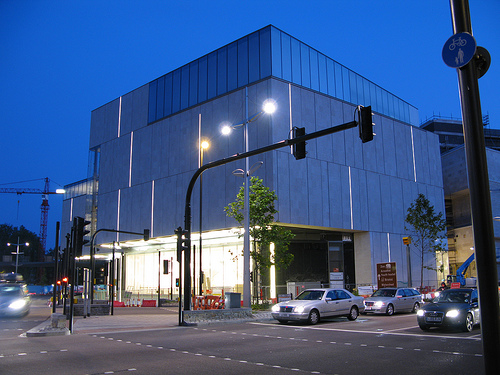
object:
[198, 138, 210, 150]
lights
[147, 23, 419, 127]
row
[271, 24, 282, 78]
window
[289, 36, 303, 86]
window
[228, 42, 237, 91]
window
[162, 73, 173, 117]
window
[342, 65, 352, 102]
window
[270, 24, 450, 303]
side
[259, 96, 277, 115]
light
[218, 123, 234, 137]
light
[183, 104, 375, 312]
light pole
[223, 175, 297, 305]
tree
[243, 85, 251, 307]
pole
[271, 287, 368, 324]
car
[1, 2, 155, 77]
blue sky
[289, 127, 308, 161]
signals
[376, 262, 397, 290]
sign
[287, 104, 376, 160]
light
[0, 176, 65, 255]
crane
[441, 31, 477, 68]
sign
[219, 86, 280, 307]
lamp post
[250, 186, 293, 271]
leaves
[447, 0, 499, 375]
pole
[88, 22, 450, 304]
building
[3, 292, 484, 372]
street